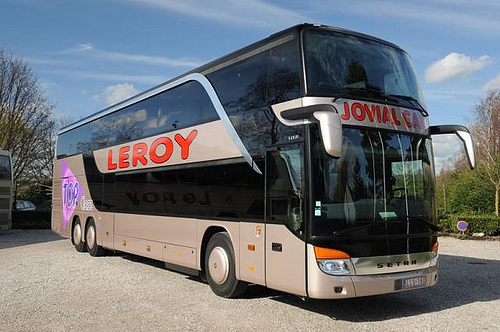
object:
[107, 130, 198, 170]
leroy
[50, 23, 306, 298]
side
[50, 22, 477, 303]
bus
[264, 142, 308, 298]
door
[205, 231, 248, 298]
tire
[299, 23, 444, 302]
front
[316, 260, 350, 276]
headlights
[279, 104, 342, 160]
mirror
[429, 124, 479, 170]
mirror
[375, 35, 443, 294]
drivers side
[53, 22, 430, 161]
roof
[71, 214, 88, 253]
tire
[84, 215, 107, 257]
tire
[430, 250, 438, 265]
headlight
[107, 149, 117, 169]
l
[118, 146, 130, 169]
e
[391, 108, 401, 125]
l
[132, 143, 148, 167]
r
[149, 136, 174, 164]
o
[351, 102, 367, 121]
o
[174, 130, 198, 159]
y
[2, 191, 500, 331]
parking lot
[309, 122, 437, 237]
windshield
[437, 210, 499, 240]
hedge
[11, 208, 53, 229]
hedge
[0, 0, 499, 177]
sky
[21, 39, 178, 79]
wispy clouds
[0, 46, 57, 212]
tree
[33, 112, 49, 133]
leaves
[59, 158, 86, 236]
decal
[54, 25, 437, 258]
windows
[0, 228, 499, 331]
gravel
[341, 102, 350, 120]
letter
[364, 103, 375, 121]
letter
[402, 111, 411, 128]
letter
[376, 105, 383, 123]
letter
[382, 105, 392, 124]
letter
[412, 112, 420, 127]
letter